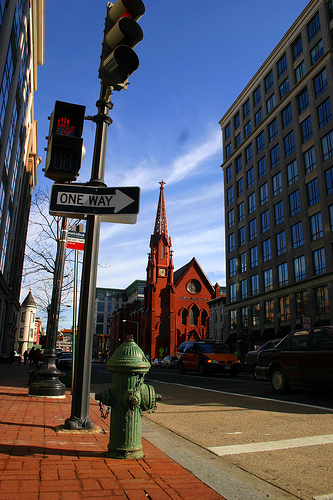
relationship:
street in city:
[56, 357, 330, 495] [4, 6, 333, 492]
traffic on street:
[85, 323, 333, 403] [56, 357, 330, 495]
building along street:
[217, 0, 333, 361] [56, 357, 330, 495]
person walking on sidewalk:
[33, 347, 43, 374] [0, 351, 218, 499]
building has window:
[107, 181, 228, 363] [189, 305, 200, 327]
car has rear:
[251, 324, 333, 401] [254, 337, 292, 390]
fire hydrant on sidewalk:
[95, 333, 163, 460] [0, 351, 218, 499]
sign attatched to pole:
[50, 184, 143, 223] [41, 4, 146, 436]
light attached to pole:
[39, 99, 88, 183] [41, 4, 146, 436]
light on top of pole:
[39, 99, 88, 183] [41, 4, 146, 436]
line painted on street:
[211, 431, 332, 458] [56, 357, 330, 495]